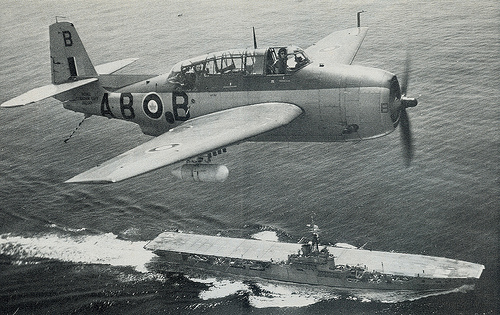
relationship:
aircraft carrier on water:
[143, 231, 484, 292] [3, 3, 497, 313]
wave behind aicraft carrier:
[5, 217, 155, 279] [141, 217, 484, 298]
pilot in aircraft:
[271, 48, 291, 75] [0, 10, 417, 184]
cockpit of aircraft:
[177, 44, 317, 74] [0, 10, 417, 184]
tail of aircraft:
[1, 16, 137, 125] [0, 10, 417, 184]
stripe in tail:
[63, 53, 80, 83] [1, 14, 145, 115]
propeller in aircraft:
[392, 35, 421, 167] [0, 10, 417, 184]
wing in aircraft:
[65, 100, 302, 183] [0, 10, 417, 184]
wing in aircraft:
[301, 9, 370, 61] [0, 10, 417, 184]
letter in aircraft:
[119, 92, 136, 120] [0, 10, 417, 184]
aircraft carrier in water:
[143, 231, 484, 292] [349, 167, 484, 239]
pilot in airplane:
[267, 48, 291, 75] [4, 39, 449, 192]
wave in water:
[0, 223, 155, 274] [29, 30, 493, 238]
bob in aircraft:
[116, 89, 195, 124] [0, 10, 417, 184]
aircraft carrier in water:
[143, 231, 484, 291] [3, 3, 497, 313]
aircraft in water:
[0, 10, 417, 184] [3, 3, 497, 313]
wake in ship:
[0, 227, 152, 276] [140, 217, 490, 294]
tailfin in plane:
[38, 16, 118, 102] [4, 13, 424, 205]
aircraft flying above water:
[0, 10, 417, 184] [3, 3, 497, 313]